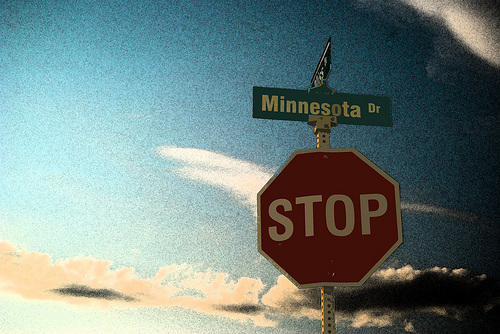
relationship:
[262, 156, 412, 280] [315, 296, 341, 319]
sign on pole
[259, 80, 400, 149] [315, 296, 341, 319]
street sign on pole